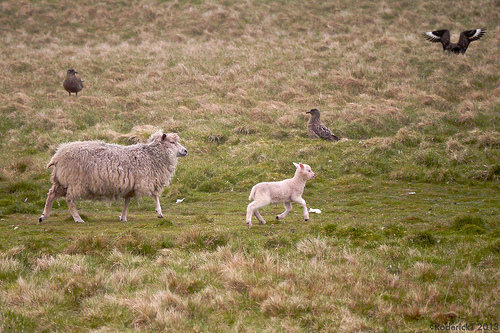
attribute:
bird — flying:
[421, 16, 489, 58]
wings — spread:
[421, 23, 486, 41]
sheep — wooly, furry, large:
[42, 120, 180, 228]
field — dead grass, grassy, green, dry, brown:
[1, 3, 493, 333]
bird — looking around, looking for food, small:
[303, 102, 342, 148]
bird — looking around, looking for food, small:
[60, 63, 86, 96]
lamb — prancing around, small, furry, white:
[239, 152, 316, 224]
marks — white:
[421, 17, 484, 42]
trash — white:
[170, 185, 419, 228]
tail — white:
[245, 187, 256, 200]